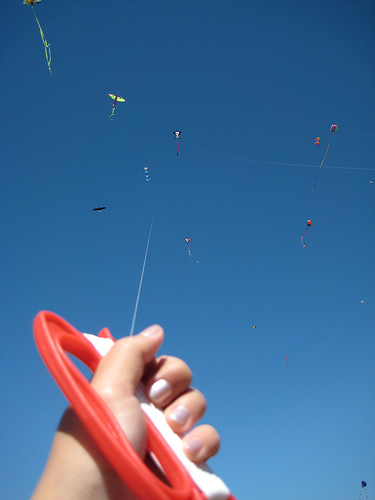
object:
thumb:
[88, 323, 163, 396]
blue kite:
[142, 165, 151, 183]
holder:
[32, 306, 240, 499]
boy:
[28, 323, 220, 498]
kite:
[107, 91, 125, 122]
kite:
[310, 123, 338, 194]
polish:
[186, 432, 201, 455]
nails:
[165, 403, 191, 428]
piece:
[81, 327, 238, 498]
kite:
[299, 216, 315, 250]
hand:
[31, 321, 221, 498]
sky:
[1, 1, 375, 499]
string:
[128, 215, 155, 335]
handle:
[31, 309, 239, 499]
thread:
[180, 134, 375, 174]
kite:
[22, 0, 56, 79]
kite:
[173, 127, 183, 157]